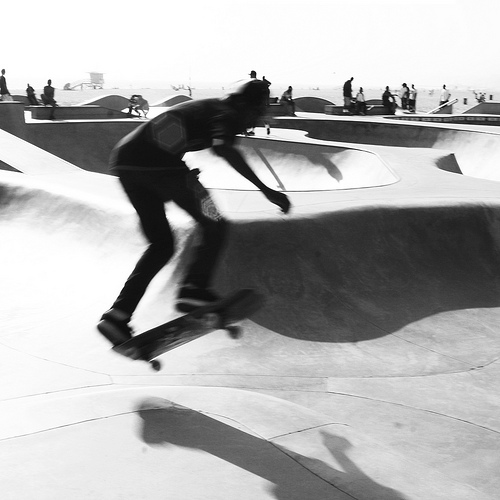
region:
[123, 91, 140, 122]
a person is standing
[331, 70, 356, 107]
a person is standing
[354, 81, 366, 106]
a person is standing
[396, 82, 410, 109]
a person is standing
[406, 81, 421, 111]
a person is standing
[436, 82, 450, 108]
a person is standing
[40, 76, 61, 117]
a person is standing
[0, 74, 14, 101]
a person is standing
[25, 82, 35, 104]
a person is standing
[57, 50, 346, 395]
a skateboarding doing a stunt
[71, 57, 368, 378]
a skateboarding doing a trick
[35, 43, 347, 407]
a skateboarding in a skatepark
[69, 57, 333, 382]
a skateboarding in the air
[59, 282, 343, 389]
a skateboard in the air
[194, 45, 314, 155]
a skateboarder with a hat on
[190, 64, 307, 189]
a person with a hat on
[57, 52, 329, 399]
a person on a skateboard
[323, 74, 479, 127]
people in the distnace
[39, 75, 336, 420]
skateboarding in the day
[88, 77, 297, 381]
a skateboarder getting air on the skateboard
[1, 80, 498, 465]
skateboarder is at a skate park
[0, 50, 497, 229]
the skate park is at the beach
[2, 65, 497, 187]
spectators and skaters are behind the skateboarder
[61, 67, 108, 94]
a lifeguard hut is on the beach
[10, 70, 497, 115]
the beach has people enjoying themselves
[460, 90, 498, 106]
barrel trash cans dot the beach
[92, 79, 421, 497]
the shadow of the skateboarder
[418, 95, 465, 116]
a skate rail at the skate park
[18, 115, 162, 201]
a half pipe at the skate park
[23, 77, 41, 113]
a person is standing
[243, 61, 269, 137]
a person is standing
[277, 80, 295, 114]
a person is standing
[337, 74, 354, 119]
a person is standing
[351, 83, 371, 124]
a person is standing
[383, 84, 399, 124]
a person is standing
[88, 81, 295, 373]
The airborne skateboarder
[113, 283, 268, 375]
Skateboard of the man in the air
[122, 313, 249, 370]
Wheels of the airborne skateboard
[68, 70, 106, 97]
The lifeguard tower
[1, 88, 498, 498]
The skateboard park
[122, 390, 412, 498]
The shadow of the airborne skateboarder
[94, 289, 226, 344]
The skateboarder's shoes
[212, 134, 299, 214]
The right arm of the skateboarder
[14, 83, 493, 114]
The sand behind the skate park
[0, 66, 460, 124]
The men standing at the edge of the skate park